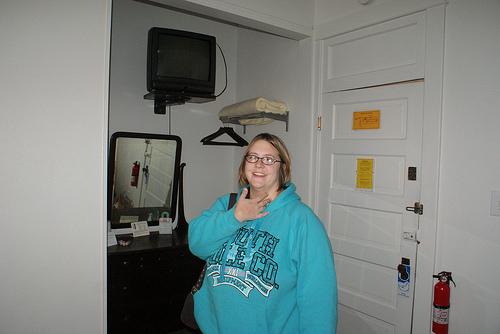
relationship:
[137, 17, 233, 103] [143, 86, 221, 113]
tv on a shelf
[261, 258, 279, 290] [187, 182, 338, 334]
letter on hoodie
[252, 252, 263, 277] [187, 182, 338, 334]
letter on hoodie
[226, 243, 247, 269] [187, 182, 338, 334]
letter on hoodie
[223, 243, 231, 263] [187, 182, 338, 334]
letter on hoodie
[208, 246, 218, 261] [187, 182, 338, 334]
letter on hoodie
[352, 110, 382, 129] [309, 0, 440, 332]
yellow sign on door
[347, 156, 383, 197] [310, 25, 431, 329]
sign on door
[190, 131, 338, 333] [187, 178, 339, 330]
girl wears hoodie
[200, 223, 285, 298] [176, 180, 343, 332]
design on hoodie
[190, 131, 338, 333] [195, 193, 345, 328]
girl wears sweatshirt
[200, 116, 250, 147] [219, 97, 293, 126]
hanger on metal shelf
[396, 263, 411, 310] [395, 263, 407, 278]
hanger on handle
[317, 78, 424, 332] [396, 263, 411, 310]
door has hanger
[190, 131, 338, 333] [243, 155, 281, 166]
girl wears eyeglasses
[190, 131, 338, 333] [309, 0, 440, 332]
girl in front of door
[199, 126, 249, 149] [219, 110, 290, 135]
hanger hanging on metal shelf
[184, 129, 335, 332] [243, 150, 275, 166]
girl wearing eyeglasses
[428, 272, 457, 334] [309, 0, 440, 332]
extinguisher by door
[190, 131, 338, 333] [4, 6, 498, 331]
girl standing in room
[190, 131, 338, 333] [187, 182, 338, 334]
girl dressed in hoodie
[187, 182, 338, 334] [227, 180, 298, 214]
hoodie has hood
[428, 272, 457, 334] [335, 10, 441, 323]
extinguisher hanging next to door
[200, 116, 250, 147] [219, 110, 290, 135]
hanger hanging on metal shelf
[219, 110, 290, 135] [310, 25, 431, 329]
metal shelf behind door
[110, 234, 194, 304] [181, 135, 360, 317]
dresser behind woman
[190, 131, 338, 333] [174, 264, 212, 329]
girl carrying purse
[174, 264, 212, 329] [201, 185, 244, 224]
purse over shoulder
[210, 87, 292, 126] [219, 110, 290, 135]
blanket on metal shelf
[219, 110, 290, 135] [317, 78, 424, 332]
metal shelf behind door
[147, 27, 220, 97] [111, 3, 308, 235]
tv mounted on wall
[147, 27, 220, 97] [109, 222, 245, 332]
tv over dresser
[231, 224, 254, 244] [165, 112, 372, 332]
letter on shirt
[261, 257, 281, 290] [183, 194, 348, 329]
letter on shirt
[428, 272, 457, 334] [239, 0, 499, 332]
extinguisher on wall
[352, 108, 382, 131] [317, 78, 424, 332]
paper on door